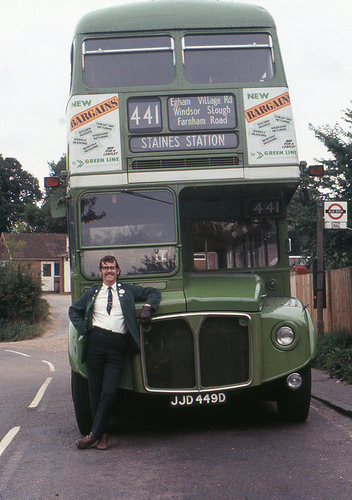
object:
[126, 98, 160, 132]
number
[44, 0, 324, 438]
bus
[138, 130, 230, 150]
route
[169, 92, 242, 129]
station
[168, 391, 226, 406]
license plate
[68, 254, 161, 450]
driver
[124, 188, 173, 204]
wiper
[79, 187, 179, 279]
windshield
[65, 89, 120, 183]
advertising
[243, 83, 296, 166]
advertising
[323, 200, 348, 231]
sign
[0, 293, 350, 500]
road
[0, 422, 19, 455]
lines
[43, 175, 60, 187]
turn signal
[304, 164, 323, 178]
turn signal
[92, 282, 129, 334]
shirt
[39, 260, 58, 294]
door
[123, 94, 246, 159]
sign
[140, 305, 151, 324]
glove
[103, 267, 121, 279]
mustache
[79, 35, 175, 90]
windshield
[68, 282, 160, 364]
jacket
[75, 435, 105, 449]
feet crossed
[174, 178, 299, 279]
no window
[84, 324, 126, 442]
pants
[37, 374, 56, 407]
edge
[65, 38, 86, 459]
edge